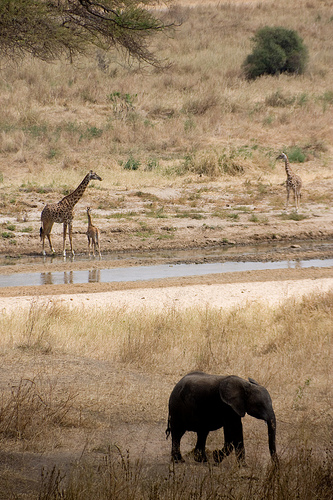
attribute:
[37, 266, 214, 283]
ripples — Small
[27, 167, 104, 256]
large giraffe — standing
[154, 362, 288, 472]
elephant — gray, walking, standing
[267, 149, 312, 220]
giraffe — standing, brown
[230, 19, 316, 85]
bush — green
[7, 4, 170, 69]
tree — green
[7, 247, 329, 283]
river — small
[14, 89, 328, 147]
vegetation — brown, overgrown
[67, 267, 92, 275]
ripples — small